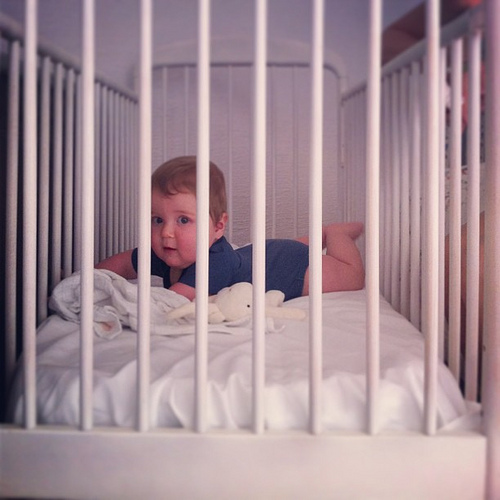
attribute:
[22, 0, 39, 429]
rail — white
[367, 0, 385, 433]
rail — white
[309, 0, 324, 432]
rail — white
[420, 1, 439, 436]
rail — white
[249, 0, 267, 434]
rail — white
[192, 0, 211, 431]
rail — white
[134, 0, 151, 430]
rail — white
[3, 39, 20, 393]
rail — white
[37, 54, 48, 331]
rail — white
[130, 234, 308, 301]
onesie — blue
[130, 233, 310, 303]
romper — blue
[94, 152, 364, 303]
baby boy — white, chubby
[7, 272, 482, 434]
crib sheet — rumpled, white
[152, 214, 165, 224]
eye — blue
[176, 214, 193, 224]
eye — blue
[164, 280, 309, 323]
rabbit toy — small, white, stuffed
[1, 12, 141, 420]
side — tall, barred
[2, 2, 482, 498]
side — tall, barred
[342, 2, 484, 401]
side — tall, barred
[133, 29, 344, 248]
side — tall, barred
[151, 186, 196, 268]
face — round, chubby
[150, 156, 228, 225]
hair — blonde, blond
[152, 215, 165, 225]
eye — blue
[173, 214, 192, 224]
eye — blue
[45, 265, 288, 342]
blanket — white, knitted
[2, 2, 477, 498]
crib — small, white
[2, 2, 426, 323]
wall — white